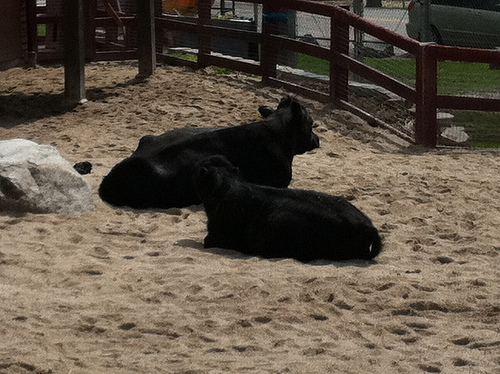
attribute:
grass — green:
[35, 20, 497, 146]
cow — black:
[177, 152, 385, 272]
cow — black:
[99, 94, 325, 209]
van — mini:
[304, 4, 489, 73]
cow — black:
[187, 154, 381, 263]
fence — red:
[33, 3, 499, 143]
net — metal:
[360, 40, 387, 65]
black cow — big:
[97, 96, 322, 216]